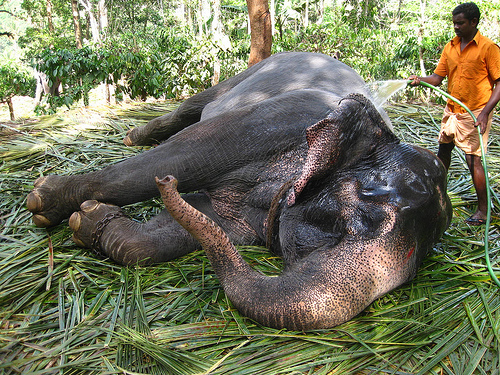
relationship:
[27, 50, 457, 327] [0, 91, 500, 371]
elephant laying on leaves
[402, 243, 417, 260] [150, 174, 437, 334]
blood on face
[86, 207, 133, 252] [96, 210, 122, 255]
chain on ankle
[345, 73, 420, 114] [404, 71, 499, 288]
water from hose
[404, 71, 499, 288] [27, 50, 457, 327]
hose spraying elephant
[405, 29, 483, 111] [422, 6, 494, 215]
shirt on man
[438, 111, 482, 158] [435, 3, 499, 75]
shorts of man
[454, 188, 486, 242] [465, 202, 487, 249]
flip flot on foot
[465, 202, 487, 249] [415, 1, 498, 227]
foot of man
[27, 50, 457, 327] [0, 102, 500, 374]
elephant on ground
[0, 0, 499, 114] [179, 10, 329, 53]
trees of tree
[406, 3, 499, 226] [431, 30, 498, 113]
man wearing orange shirt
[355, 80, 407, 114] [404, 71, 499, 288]
water coming out of hose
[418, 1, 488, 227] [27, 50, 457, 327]
man spraying an elephant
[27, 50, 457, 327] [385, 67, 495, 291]
elephant with a hose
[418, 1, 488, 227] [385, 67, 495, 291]
man spraying with hose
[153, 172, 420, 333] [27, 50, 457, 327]
trunk of an elephant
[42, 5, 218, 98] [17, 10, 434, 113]
trees in background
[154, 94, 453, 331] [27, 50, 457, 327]
elephant's forehead of elephant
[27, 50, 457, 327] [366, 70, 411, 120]
elephant getting sprayed with water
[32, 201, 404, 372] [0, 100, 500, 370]
ground in fronds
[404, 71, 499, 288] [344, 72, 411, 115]
hose spraying water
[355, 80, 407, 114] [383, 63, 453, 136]
water coming from hose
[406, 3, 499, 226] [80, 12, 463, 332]
man watering elephant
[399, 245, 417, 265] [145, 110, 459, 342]
dot on elephant's forehead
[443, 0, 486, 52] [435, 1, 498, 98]
head of man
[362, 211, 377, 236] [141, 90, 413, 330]
eye of elephant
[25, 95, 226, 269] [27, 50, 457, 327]
leg of elephant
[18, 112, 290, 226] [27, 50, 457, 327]
leg of elephant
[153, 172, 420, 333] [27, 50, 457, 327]
trunk of elephant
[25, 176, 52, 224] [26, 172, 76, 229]
nails of foot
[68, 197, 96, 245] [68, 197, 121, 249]
nails of foot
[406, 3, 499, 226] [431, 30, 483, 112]
man in shirt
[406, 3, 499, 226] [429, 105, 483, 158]
man in shorts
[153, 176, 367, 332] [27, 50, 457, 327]
trunk of elephant